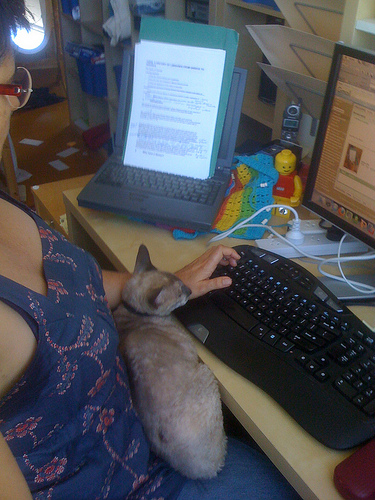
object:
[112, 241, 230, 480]
cat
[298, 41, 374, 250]
monitor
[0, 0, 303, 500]
woman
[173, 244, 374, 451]
keyboard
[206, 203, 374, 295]
power cord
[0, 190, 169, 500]
shirt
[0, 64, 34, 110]
glasses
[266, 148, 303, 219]
lego toy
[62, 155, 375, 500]
desk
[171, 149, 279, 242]
crochet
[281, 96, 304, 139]
cordless phone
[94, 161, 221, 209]
keyboard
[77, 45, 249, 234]
laptop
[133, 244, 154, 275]
ear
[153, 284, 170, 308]
ear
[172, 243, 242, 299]
hand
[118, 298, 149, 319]
collar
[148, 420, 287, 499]
lap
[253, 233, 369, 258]
power strip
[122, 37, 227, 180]
papers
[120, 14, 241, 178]
shelving unit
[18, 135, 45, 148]
evelopes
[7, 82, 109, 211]
floor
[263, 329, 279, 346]
key